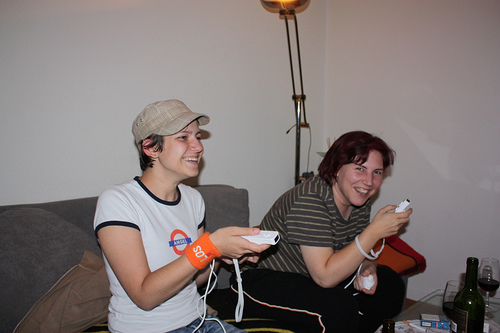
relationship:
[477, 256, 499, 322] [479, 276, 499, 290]
wine glass with wine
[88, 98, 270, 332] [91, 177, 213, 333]
woman wearing shirt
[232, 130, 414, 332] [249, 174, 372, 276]
woman wearing shirt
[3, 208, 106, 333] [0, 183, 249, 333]
cushion on sofa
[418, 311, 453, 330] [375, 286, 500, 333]
cigarette pack on coffee table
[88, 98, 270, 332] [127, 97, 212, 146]
woman wearing cap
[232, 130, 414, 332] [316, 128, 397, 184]
woman has hair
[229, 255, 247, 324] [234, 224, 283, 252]
wrist strap on game control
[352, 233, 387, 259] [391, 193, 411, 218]
wrist strap on game controller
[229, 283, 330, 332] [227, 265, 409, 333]
line on pants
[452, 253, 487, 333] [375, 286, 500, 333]
bottle on coffee table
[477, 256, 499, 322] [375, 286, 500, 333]
wine glass on coffee table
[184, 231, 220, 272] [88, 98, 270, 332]
wristband on woman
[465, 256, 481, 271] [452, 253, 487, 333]
top of bottle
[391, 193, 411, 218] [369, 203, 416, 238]
game controller in hand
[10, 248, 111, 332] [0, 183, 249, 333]
jacket on sofa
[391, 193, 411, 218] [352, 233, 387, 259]
game controller with wrist strap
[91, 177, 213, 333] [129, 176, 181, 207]
shirt has trim